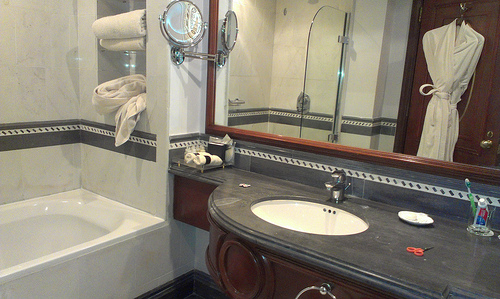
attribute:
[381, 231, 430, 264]
scisors — maroon 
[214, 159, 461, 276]
counter — black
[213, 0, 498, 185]
mirror — large  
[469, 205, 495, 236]
glass — clear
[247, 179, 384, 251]
sinkr — white 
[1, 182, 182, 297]
tub — white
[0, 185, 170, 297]
bathtub — white 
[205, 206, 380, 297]
drawers — wooden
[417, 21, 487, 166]
robe — white 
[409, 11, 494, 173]
white robe — white 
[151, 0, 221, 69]
mirror — silver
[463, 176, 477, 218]
toothbrush — green 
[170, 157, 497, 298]
counter — grey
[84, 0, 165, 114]
towel — white